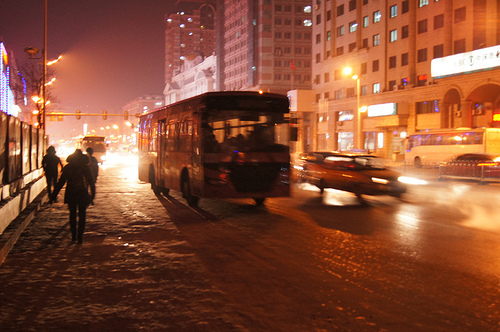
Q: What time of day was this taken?
A: Evening.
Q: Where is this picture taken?
A: On a city road.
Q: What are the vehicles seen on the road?
A: Two buses and two cars.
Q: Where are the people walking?
A: On the sidewalk of the road.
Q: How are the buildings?
A: Multistoried with many windows.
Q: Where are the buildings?
A: By the side of the road.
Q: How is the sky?
A: Dark but has a glow from the city's lights.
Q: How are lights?
A: Bright and slightly blurred.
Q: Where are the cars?
A: One on each side of the road.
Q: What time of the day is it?
A: Late in the night.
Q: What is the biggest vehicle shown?
A: A bus.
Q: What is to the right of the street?
A: High rise buildings.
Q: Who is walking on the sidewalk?
A: A group of people.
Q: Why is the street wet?
A: From the rain.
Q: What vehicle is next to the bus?
A: A car.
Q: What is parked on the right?
A: A white bus.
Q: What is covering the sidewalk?
A: Snow.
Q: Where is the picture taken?
A: City.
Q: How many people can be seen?
A: Four.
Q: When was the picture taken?
A: Night.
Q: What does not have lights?
A: Bus.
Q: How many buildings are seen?
A: Five.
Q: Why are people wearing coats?
A: Its cold.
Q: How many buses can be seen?
A: Three.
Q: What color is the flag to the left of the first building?
A: Red.